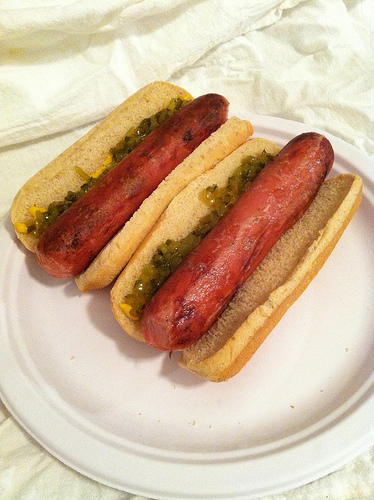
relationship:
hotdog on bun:
[34, 91, 227, 280] [15, 86, 250, 285]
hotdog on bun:
[136, 131, 334, 349] [128, 137, 361, 355]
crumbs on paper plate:
[188, 418, 191, 424] [2, 111, 374, 497]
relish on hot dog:
[206, 185, 232, 217] [107, 128, 369, 386]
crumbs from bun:
[188, 418, 197, 428] [102, 132, 363, 385]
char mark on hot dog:
[182, 129, 196, 146] [28, 85, 232, 285]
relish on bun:
[22, 74, 287, 313] [11, 75, 257, 289]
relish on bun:
[206, 185, 232, 217] [102, 132, 363, 385]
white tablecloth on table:
[220, 13, 310, 81] [3, 1, 356, 128]